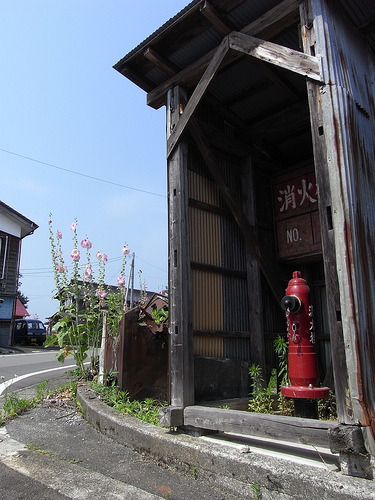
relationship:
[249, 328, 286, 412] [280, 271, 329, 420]
weeds near fire hydrant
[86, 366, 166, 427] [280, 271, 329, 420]
grass near fire hydrant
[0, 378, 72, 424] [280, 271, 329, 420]
grass near fire hydrant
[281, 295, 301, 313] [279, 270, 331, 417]
black knob on fire hydrant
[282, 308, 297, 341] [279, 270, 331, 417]
chain on fire hydrant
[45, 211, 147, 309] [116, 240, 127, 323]
flowers on stalk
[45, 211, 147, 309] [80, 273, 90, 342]
flowers on stalk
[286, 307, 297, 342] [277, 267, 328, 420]
chain on fire hydrant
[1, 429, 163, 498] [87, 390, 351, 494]
line on sidewalk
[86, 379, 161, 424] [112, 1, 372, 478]
grass near building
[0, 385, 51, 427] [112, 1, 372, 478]
grass near building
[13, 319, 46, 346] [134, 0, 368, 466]
car next to building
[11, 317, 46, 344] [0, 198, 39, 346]
car next to building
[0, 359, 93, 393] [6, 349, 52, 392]
line on street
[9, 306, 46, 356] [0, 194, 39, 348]
van next to building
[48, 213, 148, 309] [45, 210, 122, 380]
flowers on tree